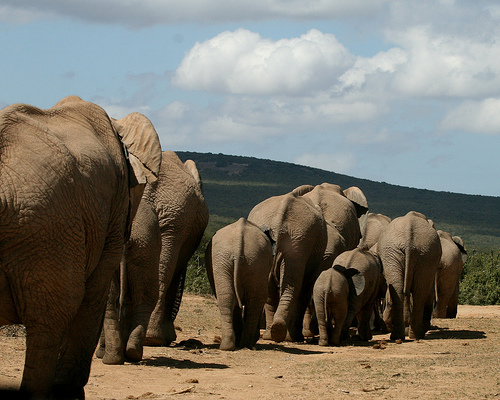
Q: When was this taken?
A: During a cloudy day.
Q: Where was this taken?
A: Outside in a verdant and dry area.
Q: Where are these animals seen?
A: In their natural surroundings.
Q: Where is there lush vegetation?
A: In front of the elephants.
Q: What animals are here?
A: Elephants.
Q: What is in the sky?
A: Clouds.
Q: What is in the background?
A: Hills.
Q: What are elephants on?
A: Ground.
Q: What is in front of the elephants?
A: Trees.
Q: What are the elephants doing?
A: Walking.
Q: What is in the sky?
A: Cloud.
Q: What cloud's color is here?
A: White.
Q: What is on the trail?
A: Dirt.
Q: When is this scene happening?
A: During the day time.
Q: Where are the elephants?
A: Field.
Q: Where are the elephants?
A: Field.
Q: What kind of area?
A: Dirt.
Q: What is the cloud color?
A: White.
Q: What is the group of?
A: Elephants.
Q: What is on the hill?
A: Trees.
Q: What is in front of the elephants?
A: Bushes.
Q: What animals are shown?
A: Elephants.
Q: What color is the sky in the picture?
A: Blue.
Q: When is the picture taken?
A: Daytime.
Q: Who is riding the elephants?
A: No one.